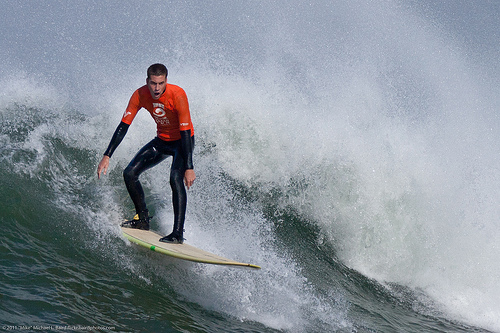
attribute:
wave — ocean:
[25, 94, 481, 294]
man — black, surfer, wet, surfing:
[89, 59, 197, 247]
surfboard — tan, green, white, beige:
[108, 217, 263, 276]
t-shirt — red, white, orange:
[120, 83, 198, 144]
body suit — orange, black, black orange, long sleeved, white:
[97, 77, 203, 236]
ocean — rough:
[4, 93, 499, 332]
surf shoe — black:
[156, 230, 186, 246]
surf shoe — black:
[117, 212, 155, 230]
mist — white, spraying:
[153, 38, 495, 314]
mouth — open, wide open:
[153, 91, 162, 98]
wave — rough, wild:
[9, 92, 335, 258]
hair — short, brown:
[144, 62, 171, 81]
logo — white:
[153, 108, 167, 117]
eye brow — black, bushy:
[157, 79, 163, 83]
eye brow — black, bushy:
[148, 78, 156, 84]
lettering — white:
[3, 324, 118, 331]